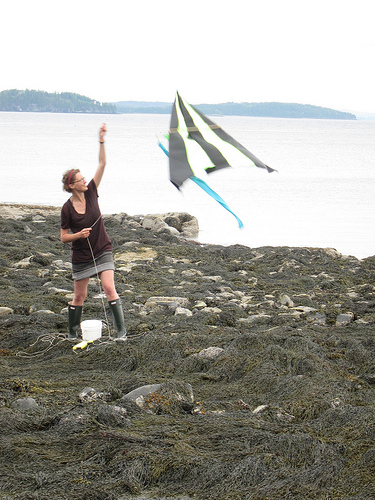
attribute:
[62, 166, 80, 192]
hairband — pink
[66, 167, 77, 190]
headband —  red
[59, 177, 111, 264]
shirt — red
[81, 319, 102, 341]
bucket —  white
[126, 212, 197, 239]
rocks —  Large,  Grey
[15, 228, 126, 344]
string — white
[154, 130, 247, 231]
tail —  blue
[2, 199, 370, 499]
cliff — rocky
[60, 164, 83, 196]
hair — brown, woman's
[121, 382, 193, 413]
rock —  Grey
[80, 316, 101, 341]
bucket — white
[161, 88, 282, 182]
kite — large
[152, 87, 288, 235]
kite — grey, white,  Yellow, blue, black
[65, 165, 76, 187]
headband — pink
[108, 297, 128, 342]
boot — black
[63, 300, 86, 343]
boot — black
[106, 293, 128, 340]
boot — black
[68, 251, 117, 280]
skirt — short